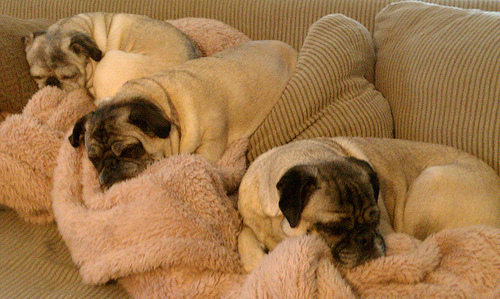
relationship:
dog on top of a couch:
[236, 137, 499, 277] [1, 1, 498, 296]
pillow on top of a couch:
[373, 1, 499, 177] [1, 1, 498, 296]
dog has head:
[236, 137, 499, 277] [275, 156, 386, 269]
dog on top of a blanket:
[236, 137, 499, 277] [1, 15, 493, 290]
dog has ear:
[236, 137, 499, 277] [274, 164, 322, 229]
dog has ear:
[66, 37, 300, 186] [125, 97, 171, 139]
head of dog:
[68, 98, 172, 194] [66, 37, 300, 186]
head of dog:
[21, 30, 102, 94] [20, 10, 203, 84]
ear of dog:
[274, 164, 322, 229] [239, 135, 499, 242]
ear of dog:
[125, 97, 171, 139] [66, 37, 300, 186]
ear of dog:
[70, 29, 102, 64] [66, 37, 300, 186]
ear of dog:
[274, 164, 322, 229] [235, 135, 498, 256]